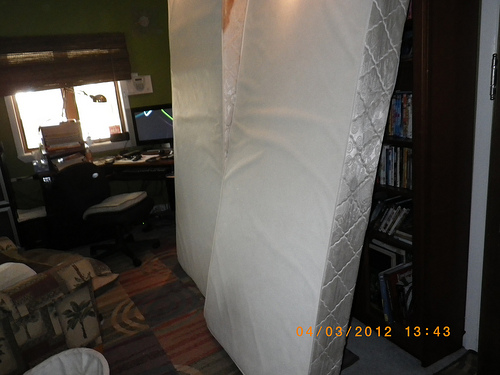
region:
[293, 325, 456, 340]
time and date of photo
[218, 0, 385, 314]
white bedding box spring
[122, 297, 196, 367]
carpet on room floor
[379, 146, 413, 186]
row of books on shelving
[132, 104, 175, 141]
screen saver on computer monitor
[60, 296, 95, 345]
design on side of chair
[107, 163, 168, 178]
white computer keyboard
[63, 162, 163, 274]
black computer chair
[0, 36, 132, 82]
brown window blinds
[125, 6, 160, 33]
white smoke detector on wall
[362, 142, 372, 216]
edge of a mattress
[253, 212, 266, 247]
part of a mattress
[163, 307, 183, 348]
part of a floor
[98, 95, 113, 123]
part of a window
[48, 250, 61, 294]
edge of a seat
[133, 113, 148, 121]
part of a screen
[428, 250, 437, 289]
edge of a shelf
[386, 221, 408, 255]
part of a shelf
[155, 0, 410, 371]
two mattress stand on a room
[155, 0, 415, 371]
mattress big and white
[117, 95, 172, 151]
screen of a computer on a desk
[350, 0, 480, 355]
shelf with books behind a mattress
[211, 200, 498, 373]
picture was taken on 2012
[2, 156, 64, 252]
chair in front a desk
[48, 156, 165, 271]
chair in front a desk has white cushion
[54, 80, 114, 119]
a lamp over a desk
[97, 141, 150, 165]
stuff on a desk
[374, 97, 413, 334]
books are in a shelf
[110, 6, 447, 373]
two white mattresses standing up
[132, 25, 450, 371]
two mattressing standing up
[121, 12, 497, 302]
two mattresses leaning on bookshelf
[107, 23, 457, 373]
two mattress inside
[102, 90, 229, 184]
a computer monitor on desk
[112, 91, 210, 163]
a screen saver on monitor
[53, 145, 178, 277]
a rolling black chair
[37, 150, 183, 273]
a rolling computer chair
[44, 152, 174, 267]
a rolling office chair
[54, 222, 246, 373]
a multicolor rug on floor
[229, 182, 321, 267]
the bed is white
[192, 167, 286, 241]
the bed is white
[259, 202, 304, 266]
the bed is white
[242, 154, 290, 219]
the bed is white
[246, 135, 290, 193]
the bed is white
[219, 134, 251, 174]
the bed is white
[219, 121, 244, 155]
the bed is white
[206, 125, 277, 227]
the bed is white